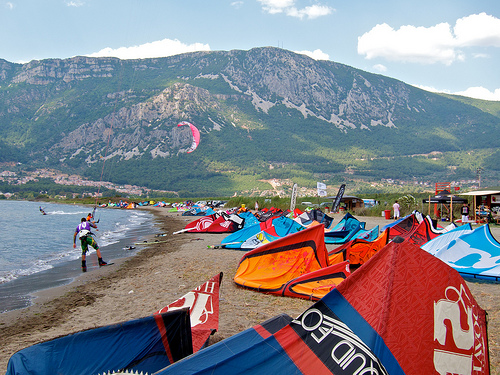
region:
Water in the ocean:
[3, 213, 59, 341]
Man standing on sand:
[70, 218, 124, 266]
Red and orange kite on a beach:
[232, 231, 387, 295]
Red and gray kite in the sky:
[166, 116, 211, 164]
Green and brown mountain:
[71, 42, 386, 174]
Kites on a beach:
[158, 188, 421, 354]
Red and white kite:
[180, 212, 251, 228]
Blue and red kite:
[205, 209, 324, 252]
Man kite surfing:
[24, 191, 58, 229]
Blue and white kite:
[401, 215, 498, 268]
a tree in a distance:
[87, 153, 95, 163]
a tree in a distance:
[109, 170, 116, 182]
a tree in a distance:
[136, 176, 144, 191]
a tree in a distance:
[140, 155, 150, 163]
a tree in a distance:
[103, 180, 116, 195]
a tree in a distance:
[207, 162, 213, 182]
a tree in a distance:
[239, 192, 247, 203]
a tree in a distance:
[316, 162, 319, 172]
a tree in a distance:
[365, 157, 378, 174]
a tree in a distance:
[411, 152, 417, 165]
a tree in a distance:
[8, 107, 14, 118]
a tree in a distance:
[19, 184, 29, 197]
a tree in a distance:
[49, 181, 61, 193]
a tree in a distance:
[62, 184, 75, 202]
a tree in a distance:
[23, 183, 32, 190]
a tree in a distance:
[121, 177, 125, 185]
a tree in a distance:
[148, 175, 155, 186]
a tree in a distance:
[198, 160, 206, 174]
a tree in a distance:
[185, 190, 195, 196]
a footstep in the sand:
[63, 310, 93, 322]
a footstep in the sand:
[45, 313, 55, 325]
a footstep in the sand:
[19, 330, 31, 338]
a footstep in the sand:
[39, 316, 56, 333]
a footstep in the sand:
[108, 270, 117, 277]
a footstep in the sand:
[237, 300, 249, 309]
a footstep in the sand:
[176, 245, 189, 265]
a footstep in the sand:
[117, 276, 129, 286]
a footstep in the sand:
[43, 320, 53, 332]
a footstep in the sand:
[486, 335, 499, 355]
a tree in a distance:
[113, 147, 125, 174]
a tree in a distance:
[146, 122, 156, 132]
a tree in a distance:
[131, 169, 142, 180]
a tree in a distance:
[152, 170, 158, 180]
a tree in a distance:
[171, 182, 183, 194]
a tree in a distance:
[186, 161, 191, 169]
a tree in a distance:
[200, 171, 205, 181]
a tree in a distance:
[186, 192, 190, 199]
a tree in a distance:
[23, 180, 29, 188]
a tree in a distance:
[321, 162, 329, 175]